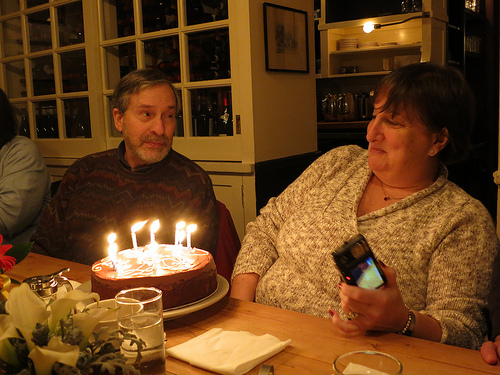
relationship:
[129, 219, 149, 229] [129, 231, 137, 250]
flame on top of candle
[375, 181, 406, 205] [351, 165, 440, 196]
necklace around womans neck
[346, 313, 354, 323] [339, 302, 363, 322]
ring on finger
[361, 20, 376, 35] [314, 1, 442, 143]
bulb on in background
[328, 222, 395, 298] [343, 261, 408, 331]
camera in hand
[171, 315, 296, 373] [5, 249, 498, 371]
napkin on table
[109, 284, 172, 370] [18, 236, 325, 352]
glass on table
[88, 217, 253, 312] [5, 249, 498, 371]
cake on table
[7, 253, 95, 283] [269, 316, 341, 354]
flowers on table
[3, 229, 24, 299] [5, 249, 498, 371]
flower on table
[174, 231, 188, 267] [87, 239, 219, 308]
candle on cake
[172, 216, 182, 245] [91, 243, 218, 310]
candle on cake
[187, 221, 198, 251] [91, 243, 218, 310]
candle on cake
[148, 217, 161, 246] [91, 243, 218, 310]
candle on cake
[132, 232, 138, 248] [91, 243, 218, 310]
candle on cake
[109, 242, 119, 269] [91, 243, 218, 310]
candle on cake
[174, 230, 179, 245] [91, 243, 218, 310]
candle on cake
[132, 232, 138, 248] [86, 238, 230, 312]
candle on cake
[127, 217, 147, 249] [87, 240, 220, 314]
candle on cake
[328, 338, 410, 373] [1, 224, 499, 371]
glass on table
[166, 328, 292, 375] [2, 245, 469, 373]
napkin on table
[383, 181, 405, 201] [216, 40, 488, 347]
necklace on woman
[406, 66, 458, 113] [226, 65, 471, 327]
hair on woman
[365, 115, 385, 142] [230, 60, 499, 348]
nose on woman